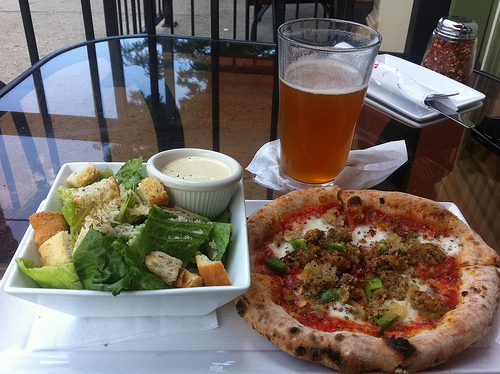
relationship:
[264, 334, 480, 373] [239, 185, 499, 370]
crust of pizza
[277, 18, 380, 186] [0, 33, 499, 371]
glass on table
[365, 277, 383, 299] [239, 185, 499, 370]
pepper on pizza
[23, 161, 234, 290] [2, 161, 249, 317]
salad in bowl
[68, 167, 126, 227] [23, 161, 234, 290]
croutons on salad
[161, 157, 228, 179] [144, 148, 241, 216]
dressing in bowl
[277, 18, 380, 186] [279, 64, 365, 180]
glass of beverage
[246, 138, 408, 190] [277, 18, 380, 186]
napkin under glass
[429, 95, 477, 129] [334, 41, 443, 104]
silverwarre wrapped  in napkin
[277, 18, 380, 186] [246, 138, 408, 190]
glass on napkin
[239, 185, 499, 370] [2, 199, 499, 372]
pizza on plate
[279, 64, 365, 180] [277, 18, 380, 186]
iced tea in a glass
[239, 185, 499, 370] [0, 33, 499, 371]
pizza on table